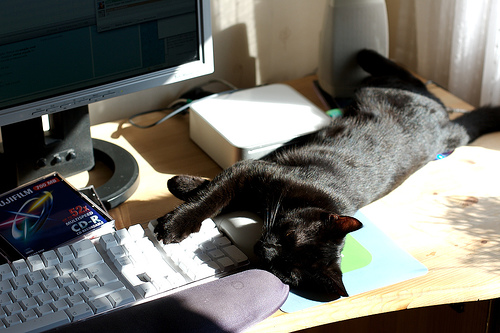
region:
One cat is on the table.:
[249, 164, 368, 276]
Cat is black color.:
[289, 164, 373, 251]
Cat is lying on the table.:
[271, 169, 403, 298]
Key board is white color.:
[35, 245, 154, 313]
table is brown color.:
[416, 205, 488, 281]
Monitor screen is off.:
[17, 16, 165, 164]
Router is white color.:
[192, 114, 314, 186]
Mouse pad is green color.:
[361, 243, 428, 282]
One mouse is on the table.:
[212, 208, 275, 262]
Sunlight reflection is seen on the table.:
[66, 91, 485, 288]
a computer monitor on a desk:
[0, 0, 218, 217]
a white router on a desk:
[162, 75, 326, 166]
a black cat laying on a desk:
[141, 44, 498, 297]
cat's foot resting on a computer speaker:
[316, 0, 416, 100]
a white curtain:
[383, 0, 497, 105]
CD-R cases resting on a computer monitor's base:
[0, 158, 118, 255]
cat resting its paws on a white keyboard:
[1, 191, 253, 327]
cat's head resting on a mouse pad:
[261, 198, 433, 309]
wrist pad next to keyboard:
[29, 260, 294, 331]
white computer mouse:
[210, 198, 263, 251]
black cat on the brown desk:
[158, 50, 498, 308]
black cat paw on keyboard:
[149, 206, 237, 278]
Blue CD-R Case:
[1, 171, 111, 245]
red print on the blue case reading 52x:
[57, 198, 90, 223]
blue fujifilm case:
[2, 171, 112, 236]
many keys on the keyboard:
[2, 255, 144, 301]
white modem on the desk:
[134, 81, 331, 148]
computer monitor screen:
[1, 2, 217, 121]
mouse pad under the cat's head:
[288, 209, 428, 309]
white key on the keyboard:
[108, 242, 127, 257]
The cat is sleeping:
[150, 112, 381, 314]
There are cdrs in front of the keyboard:
[12, 183, 146, 250]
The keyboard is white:
[13, 264, 179, 326]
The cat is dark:
[221, 174, 366, 330]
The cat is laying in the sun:
[235, 50, 422, 332]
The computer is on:
[20, 8, 243, 107]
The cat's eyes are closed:
[263, 202, 333, 323]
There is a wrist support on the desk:
[78, 257, 275, 330]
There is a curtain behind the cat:
[395, 2, 499, 83]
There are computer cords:
[87, 75, 300, 181]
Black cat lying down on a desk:
[151, 41, 496, 297]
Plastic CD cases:
[0, 166, 116, 263]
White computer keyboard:
[0, 196, 255, 328]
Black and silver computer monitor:
[0, 0, 215, 210]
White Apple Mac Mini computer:
[185, 71, 340, 176]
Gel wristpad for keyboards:
[40, 265, 295, 330]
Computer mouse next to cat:
[191, 176, 268, 246]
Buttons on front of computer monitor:
[21, 81, 118, 116]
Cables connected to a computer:
[120, 72, 245, 132]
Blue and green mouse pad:
[235, 201, 435, 316]